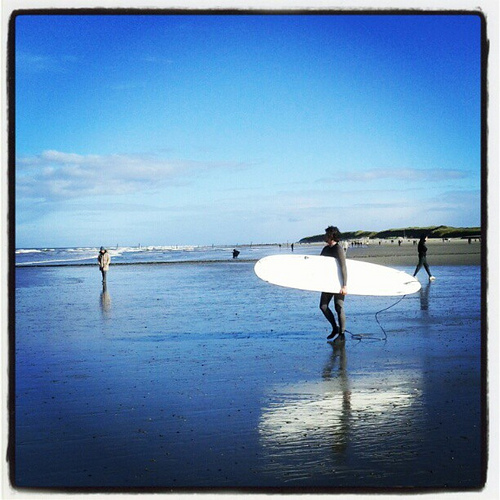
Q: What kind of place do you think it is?
A: It is an ocean.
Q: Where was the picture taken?
A: It was taken at the ocean.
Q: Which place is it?
A: It is an ocean.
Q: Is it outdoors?
A: Yes, it is outdoors.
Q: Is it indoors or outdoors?
A: It is outdoors.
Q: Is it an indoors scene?
A: No, it is outdoors.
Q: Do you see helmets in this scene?
A: No, there are no helmets.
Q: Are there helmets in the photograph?
A: No, there are no helmets.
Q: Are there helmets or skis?
A: No, there are no helmets or skis.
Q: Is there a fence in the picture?
A: No, there are no fences.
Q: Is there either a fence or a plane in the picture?
A: No, there are no fences or airplanes.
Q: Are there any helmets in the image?
A: No, there are no helmets.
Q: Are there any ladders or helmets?
A: No, there are no helmets or ladders.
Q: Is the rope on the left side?
A: No, the rope is on the right of the image.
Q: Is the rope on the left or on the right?
A: The rope is on the right of the image.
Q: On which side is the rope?
A: The rope is on the right of the image.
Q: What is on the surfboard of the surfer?
A: The rope is on the surfboard.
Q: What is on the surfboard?
A: The rope is on the surfboard.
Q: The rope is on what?
A: The rope is on the surf board.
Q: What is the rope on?
A: The rope is on the surf board.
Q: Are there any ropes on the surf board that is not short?
A: Yes, there is a rope on the surfboard.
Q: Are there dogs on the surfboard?
A: No, there is a rope on the surfboard.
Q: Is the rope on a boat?
A: No, the rope is on the surfboard.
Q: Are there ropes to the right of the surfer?
A: Yes, there is a rope to the right of the surfer.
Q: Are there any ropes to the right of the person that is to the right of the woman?
A: Yes, there is a rope to the right of the surfer.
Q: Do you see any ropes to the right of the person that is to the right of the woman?
A: Yes, there is a rope to the right of the surfer.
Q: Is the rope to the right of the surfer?
A: Yes, the rope is to the right of the surfer.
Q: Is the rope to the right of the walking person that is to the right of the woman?
A: Yes, the rope is to the right of the surfer.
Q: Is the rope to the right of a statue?
A: No, the rope is to the right of the surfer.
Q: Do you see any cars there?
A: No, there are no cars.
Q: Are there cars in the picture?
A: No, there are no cars.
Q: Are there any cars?
A: No, there are no cars.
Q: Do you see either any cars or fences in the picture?
A: No, there are no cars or fences.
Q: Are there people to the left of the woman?
A: Yes, there is a person to the left of the woman.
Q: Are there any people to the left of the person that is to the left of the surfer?
A: Yes, there is a person to the left of the woman.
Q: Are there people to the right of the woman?
A: No, the person is to the left of the woman.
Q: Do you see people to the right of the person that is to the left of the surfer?
A: No, the person is to the left of the woman.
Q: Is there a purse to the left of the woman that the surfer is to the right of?
A: No, there is a person to the left of the woman.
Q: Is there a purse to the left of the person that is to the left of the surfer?
A: No, there is a person to the left of the woman.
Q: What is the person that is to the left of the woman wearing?
A: The person is wearing a jacket.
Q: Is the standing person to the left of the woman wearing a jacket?
A: Yes, the person is wearing a jacket.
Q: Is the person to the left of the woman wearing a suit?
A: No, the person is wearing a jacket.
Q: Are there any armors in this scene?
A: No, there are no armors.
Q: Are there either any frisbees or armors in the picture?
A: No, there are no armors or frisbees.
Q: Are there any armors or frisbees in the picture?
A: No, there are no armors or frisbees.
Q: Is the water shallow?
A: Yes, the water is shallow.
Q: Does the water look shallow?
A: Yes, the water is shallow.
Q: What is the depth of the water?
A: The water is shallow.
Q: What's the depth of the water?
A: The water is shallow.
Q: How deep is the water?
A: The water is shallow.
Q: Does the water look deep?
A: No, the water is shallow.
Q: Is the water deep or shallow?
A: The water is shallow.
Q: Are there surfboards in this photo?
A: Yes, there is a surfboard.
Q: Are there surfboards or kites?
A: Yes, there is a surfboard.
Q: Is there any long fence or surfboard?
A: Yes, there is a long surfboard.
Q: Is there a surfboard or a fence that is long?
A: Yes, the surfboard is long.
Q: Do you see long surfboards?
A: Yes, there is a long surfboard.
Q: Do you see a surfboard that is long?
A: Yes, there is a surfboard that is long.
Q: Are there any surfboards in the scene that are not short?
A: Yes, there is a long surfboard.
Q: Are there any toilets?
A: No, there are no toilets.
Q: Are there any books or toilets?
A: No, there are no toilets or books.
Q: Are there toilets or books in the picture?
A: No, there are no toilets or books.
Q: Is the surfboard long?
A: Yes, the surfboard is long.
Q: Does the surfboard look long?
A: Yes, the surfboard is long.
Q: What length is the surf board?
A: The surf board is long.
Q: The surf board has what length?
A: The surf board is long.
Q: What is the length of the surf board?
A: The surf board is long.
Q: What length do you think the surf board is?
A: The surf board is long.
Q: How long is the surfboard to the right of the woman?
A: The surfboard is long.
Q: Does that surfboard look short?
A: No, the surfboard is long.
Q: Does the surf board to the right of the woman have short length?
A: No, the surfboard is long.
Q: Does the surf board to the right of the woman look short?
A: No, the surfboard is long.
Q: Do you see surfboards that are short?
A: No, there is a surfboard but it is long.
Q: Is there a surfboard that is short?
A: No, there is a surfboard but it is long.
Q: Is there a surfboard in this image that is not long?
A: No, there is a surfboard but it is long.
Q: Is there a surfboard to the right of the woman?
A: Yes, there is a surfboard to the right of the woman.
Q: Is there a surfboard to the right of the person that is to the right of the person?
A: Yes, there is a surfboard to the right of the woman.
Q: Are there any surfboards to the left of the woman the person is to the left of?
A: No, the surfboard is to the right of the woman.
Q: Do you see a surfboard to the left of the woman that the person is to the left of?
A: No, the surfboard is to the right of the woman.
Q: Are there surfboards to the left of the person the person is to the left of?
A: No, the surfboard is to the right of the woman.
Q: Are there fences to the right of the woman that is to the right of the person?
A: No, there is a surfboard to the right of the woman.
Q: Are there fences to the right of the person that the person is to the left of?
A: No, there is a surfboard to the right of the woman.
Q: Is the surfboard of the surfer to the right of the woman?
A: Yes, the surf board is to the right of the woman.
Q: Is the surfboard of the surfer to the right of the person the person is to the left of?
A: Yes, the surf board is to the right of the woman.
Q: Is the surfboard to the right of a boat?
A: No, the surfboard is to the right of the woman.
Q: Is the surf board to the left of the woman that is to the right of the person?
A: No, the surf board is to the right of the woman.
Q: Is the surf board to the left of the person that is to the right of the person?
A: No, the surf board is to the right of the woman.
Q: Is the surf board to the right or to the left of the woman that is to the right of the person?
A: The surf board is to the right of the woman.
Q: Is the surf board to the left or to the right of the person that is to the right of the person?
A: The surf board is to the right of the woman.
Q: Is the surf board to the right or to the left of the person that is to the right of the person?
A: The surf board is to the right of the woman.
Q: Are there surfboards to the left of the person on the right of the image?
A: Yes, there is a surfboard to the left of the person.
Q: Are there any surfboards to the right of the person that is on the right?
A: No, the surfboard is to the left of the person.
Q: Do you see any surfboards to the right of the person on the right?
A: No, the surfboard is to the left of the person.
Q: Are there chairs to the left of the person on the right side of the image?
A: No, there is a surfboard to the left of the person.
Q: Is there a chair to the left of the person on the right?
A: No, there is a surfboard to the left of the person.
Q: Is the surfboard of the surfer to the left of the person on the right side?
A: Yes, the surfboard is to the left of the person.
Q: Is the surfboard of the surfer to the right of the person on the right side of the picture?
A: No, the surfboard is to the left of the person.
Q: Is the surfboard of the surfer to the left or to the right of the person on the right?
A: The surfboard is to the left of the person.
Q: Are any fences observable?
A: No, there are no fences.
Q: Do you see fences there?
A: No, there are no fences.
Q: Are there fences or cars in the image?
A: No, there are no fences or cars.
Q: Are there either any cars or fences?
A: No, there are no fences or cars.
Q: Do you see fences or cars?
A: No, there are no fences or cars.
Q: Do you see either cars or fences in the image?
A: No, there are no fences or cars.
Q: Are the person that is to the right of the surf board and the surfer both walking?
A: Yes, both the person and the surfer are walking.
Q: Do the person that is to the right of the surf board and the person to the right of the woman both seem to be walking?
A: Yes, both the person and the surfer are walking.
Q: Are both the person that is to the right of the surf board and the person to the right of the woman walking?
A: Yes, both the person and the surfer are walking.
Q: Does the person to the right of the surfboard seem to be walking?
A: Yes, the person is walking.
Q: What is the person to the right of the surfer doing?
A: The person is walking.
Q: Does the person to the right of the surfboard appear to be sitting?
A: No, the person is walking.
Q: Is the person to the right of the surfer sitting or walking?
A: The person is walking.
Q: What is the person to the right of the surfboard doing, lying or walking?
A: The person is walking.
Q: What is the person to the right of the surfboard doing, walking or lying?
A: The person is walking.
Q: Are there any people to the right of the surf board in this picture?
A: Yes, there is a person to the right of the surf board.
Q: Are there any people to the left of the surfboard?
A: No, the person is to the right of the surfboard.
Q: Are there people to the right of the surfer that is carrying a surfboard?
A: Yes, there is a person to the right of the surfer.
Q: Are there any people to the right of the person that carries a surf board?
A: Yes, there is a person to the right of the surfer.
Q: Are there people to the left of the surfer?
A: No, the person is to the right of the surfer.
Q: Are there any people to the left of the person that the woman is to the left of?
A: No, the person is to the right of the surfer.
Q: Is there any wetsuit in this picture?
A: Yes, there is a wetsuit.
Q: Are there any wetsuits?
A: Yes, there is a wetsuit.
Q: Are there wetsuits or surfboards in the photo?
A: Yes, there is a wetsuit.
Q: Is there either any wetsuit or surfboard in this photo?
A: Yes, there is a wetsuit.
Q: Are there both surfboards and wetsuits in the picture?
A: Yes, there are both a wetsuit and a surfboard.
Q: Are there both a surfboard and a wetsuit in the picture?
A: Yes, there are both a wetsuit and a surfboard.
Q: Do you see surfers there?
A: Yes, there is a surfer.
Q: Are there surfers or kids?
A: Yes, there is a surfer.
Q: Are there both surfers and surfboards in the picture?
A: Yes, there are both a surfer and a surfboard.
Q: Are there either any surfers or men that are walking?
A: Yes, the surfer is walking.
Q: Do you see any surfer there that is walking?
A: Yes, there is a surfer that is walking.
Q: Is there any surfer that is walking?
A: Yes, there is a surfer that is walking.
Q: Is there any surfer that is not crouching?
A: Yes, there is a surfer that is walking.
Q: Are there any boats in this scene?
A: No, there are no boats.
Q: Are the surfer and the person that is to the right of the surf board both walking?
A: Yes, both the surfer and the person are walking.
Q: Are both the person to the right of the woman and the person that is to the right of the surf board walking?
A: Yes, both the surfer and the person are walking.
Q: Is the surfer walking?
A: Yes, the surfer is walking.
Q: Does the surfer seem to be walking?
A: Yes, the surfer is walking.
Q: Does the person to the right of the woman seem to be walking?
A: Yes, the surfer is walking.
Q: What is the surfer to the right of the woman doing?
A: The surfer is walking.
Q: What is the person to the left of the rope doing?
A: The surfer is walking.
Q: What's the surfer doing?
A: The surfer is walking.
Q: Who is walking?
A: The surfer is walking.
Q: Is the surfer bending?
A: No, the surfer is walking.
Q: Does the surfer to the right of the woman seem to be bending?
A: No, the surfer is walking.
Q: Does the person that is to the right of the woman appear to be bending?
A: No, the surfer is walking.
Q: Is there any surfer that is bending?
A: No, there is a surfer but he is walking.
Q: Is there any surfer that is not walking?
A: No, there is a surfer but he is walking.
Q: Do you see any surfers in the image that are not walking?
A: No, there is a surfer but he is walking.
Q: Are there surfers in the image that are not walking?
A: No, there is a surfer but he is walking.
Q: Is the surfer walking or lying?
A: The surfer is walking.